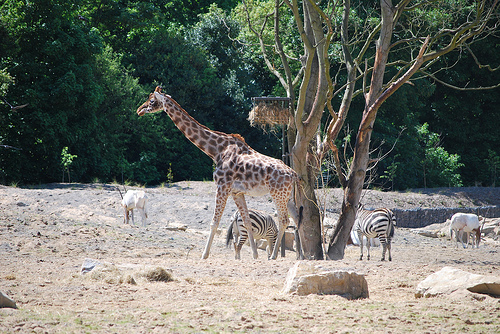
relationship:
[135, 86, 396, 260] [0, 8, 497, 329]
animals in zoo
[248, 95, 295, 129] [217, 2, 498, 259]
giraffe hopper high on a tree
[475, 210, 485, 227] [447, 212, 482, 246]
horns on antelope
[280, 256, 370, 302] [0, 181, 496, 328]
rock on ground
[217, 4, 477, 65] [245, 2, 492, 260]
leaves on tree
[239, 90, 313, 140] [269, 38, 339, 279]
giraffe hopper in tree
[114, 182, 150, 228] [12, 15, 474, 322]
white antelope in zoo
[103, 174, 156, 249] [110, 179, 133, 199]
white antelope has horns